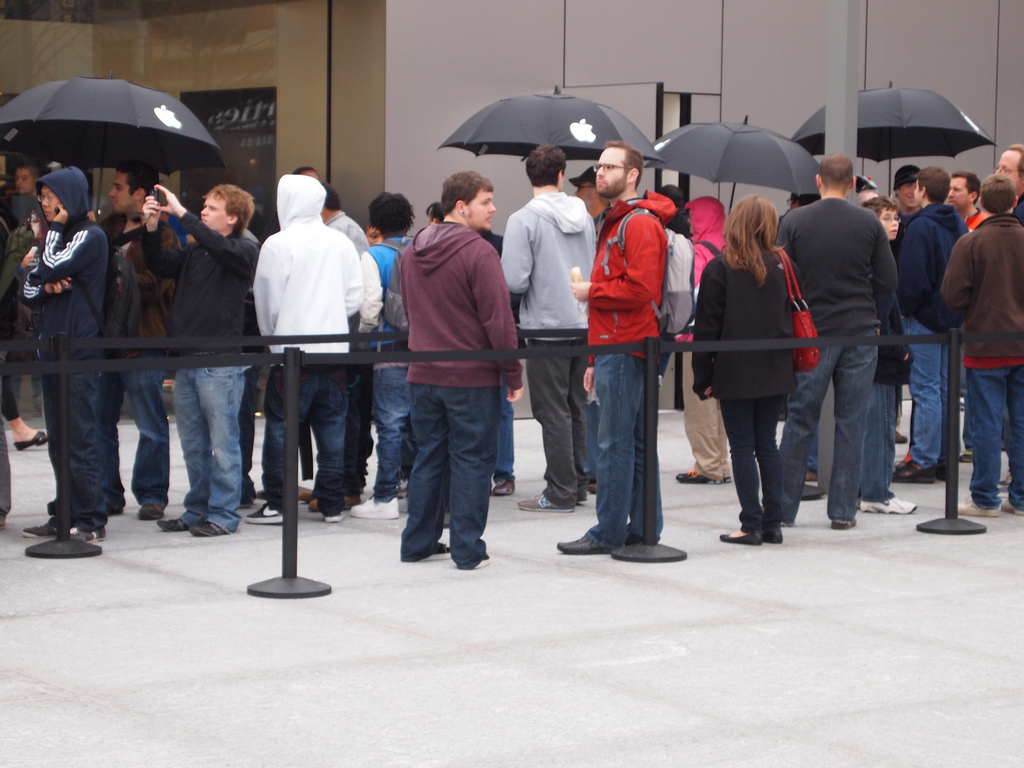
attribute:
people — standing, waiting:
[5, 131, 1022, 571]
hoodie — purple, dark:
[392, 213, 531, 401]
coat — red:
[577, 187, 684, 358]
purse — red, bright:
[773, 241, 833, 372]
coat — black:
[690, 236, 802, 398]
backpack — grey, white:
[622, 203, 704, 342]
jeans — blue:
[583, 349, 675, 552]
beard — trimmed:
[595, 173, 630, 200]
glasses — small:
[590, 155, 633, 176]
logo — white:
[563, 111, 599, 146]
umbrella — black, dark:
[6, 71, 231, 178]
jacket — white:
[242, 170, 371, 353]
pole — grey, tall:
[817, 4, 866, 157]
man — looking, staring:
[553, 136, 701, 563]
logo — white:
[149, 96, 186, 129]